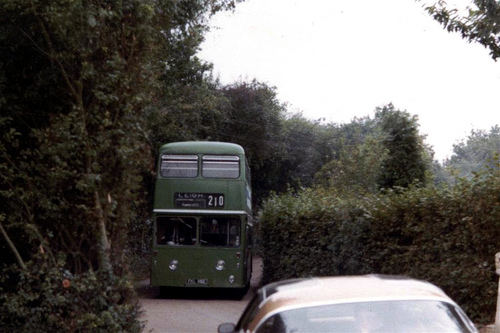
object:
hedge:
[289, 186, 499, 296]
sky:
[253, 0, 417, 72]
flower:
[58, 276, 77, 290]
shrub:
[0, 216, 154, 330]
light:
[215, 257, 228, 271]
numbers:
[207, 195, 214, 206]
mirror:
[214, 316, 235, 330]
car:
[212, 271, 484, 333]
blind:
[159, 151, 200, 178]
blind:
[200, 151, 241, 179]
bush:
[272, 189, 482, 272]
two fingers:
[146, 135, 259, 303]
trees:
[268, 74, 478, 279]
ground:
[159, 298, 227, 321]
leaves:
[350, 165, 378, 188]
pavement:
[154, 302, 197, 331]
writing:
[206, 194, 225, 207]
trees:
[0, 0, 147, 332]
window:
[198, 214, 243, 249]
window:
[154, 213, 197, 246]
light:
[165, 259, 180, 273]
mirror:
[243, 208, 258, 234]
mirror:
[141, 208, 153, 232]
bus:
[146, 137, 260, 303]